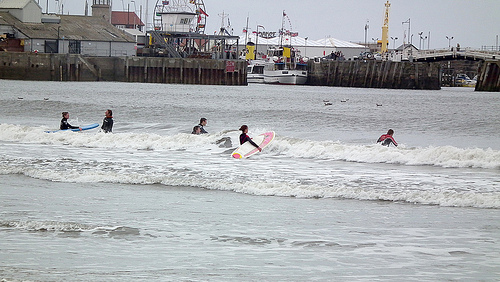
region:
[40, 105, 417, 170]
A group of surfers in the ocean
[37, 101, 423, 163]
A group of surfers in the ocean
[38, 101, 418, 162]
A group of surfers in the ocean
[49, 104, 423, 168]
A group of surfers in the ocean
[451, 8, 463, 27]
There is a gray sky here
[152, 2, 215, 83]
There is a ferris wheel here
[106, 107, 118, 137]
This person has a had full of brown hair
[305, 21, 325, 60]
There are white tents in the background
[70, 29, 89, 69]
There is a white building visible here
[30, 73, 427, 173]
a group of people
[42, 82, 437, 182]
a group of persons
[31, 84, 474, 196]
a group of people in water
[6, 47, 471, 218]
a group of people swimming in water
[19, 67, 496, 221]
a group of people skating in water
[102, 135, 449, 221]
a flow of water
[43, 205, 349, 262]
water coming out of sea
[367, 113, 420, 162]
a man in the water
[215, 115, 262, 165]
a man holding the board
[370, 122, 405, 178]
person is in the water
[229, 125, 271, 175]
person is in the water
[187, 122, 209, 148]
person is in the water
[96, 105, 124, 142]
person is in the water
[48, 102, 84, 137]
person is in the water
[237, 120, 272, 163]
person holding a surfboard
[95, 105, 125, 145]
person is wearing a wet suit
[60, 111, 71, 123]
person is wearing a wet suit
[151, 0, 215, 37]
Ferris wheel on pier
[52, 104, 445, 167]
several surfers in the water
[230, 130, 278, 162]
an orange and white surfboard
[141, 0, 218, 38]
a ferris wheel on the beach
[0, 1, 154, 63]
a house on the beach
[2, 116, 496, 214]
white waves in the water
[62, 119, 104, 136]
blue surfboard in the water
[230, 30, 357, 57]
white buildings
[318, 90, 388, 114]
birds flying by the water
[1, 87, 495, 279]
rippling gray ocean water